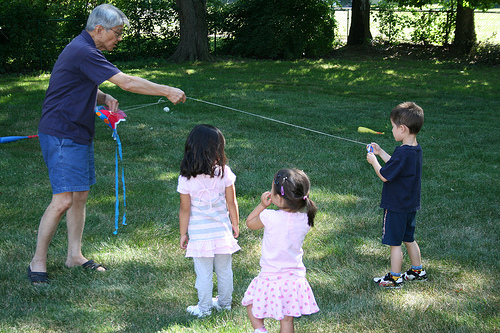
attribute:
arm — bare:
[106, 69, 166, 99]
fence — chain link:
[325, 3, 497, 50]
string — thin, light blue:
[184, 97, 383, 159]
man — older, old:
[28, 2, 187, 287]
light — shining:
[183, 65, 198, 75]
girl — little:
[243, 165, 328, 331]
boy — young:
[342, 77, 437, 298]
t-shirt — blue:
[375, 141, 425, 213]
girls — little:
[177, 122, 319, 331]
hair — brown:
[280, 172, 309, 205]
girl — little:
[239, 162, 329, 319]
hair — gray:
[84, 1, 133, 33]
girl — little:
[179, 124, 240, 315]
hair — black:
[180, 122, 226, 179]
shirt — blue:
[176, 165, 241, 255]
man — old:
[44, 38, 104, 223]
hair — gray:
[82, 2, 126, 26]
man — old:
[41, 32, 96, 272]